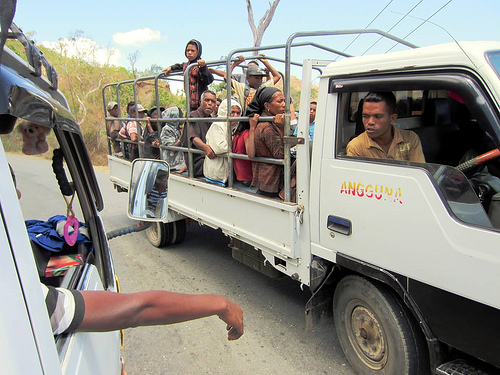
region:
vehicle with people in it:
[98, 40, 480, 318]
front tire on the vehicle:
[323, 272, 424, 367]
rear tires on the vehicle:
[120, 195, 184, 256]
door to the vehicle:
[313, 80, 478, 270]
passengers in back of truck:
[99, 63, 293, 176]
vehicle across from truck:
[2, 31, 124, 372]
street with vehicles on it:
[3, 163, 291, 364]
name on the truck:
[324, 165, 409, 210]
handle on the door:
[321, 211, 354, 238]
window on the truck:
[367, 159, 487, 221]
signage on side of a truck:
[339, 178, 404, 204]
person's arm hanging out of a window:
[39, 282, 246, 341]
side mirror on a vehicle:
[127, 157, 169, 221]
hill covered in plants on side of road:
[7, 37, 311, 166]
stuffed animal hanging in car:
[16, 119, 50, 155]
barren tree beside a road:
[244, 0, 279, 61]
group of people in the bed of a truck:
[103, 40, 315, 203]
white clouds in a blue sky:
[11, 0, 498, 85]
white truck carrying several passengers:
[101, 28, 498, 371]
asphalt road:
[4, 151, 361, 373]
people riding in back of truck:
[104, 42, 315, 200]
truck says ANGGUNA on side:
[338, 179, 405, 204]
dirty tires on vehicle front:
[327, 272, 426, 374]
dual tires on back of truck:
[143, 216, 189, 246]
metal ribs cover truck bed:
[86, 27, 418, 203]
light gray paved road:
[6, 149, 356, 374]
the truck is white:
[101, 49, 494, 372]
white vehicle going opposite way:
[0, 4, 127, 374]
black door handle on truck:
[326, 215, 354, 237]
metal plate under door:
[423, 357, 489, 374]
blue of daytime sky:
[23, 0, 496, 66]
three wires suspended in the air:
[343, 2, 448, 55]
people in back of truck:
[100, 26, 497, 370]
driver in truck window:
[315, 82, 494, 284]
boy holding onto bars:
[157, 37, 214, 107]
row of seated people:
[110, 91, 290, 196]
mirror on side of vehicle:
[106, 158, 172, 243]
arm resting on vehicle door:
[0, 110, 245, 359]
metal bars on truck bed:
[104, 28, 416, 200]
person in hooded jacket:
[203, 99, 240, 184]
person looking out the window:
[353, 90, 425, 179]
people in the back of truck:
[111, 59, 322, 165]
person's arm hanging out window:
[21, 272, 289, 345]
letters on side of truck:
[318, 172, 425, 212]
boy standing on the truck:
[180, 33, 199, 105]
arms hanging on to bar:
[221, 53, 280, 80]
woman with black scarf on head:
[249, 88, 286, 121]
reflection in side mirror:
[131, 145, 171, 225]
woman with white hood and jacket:
[208, 97, 240, 184]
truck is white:
[296, 174, 493, 257]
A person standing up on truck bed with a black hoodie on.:
[161, 39, 214, 111]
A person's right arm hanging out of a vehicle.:
[36, 277, 246, 342]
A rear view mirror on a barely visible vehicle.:
[126, 159, 171, 224]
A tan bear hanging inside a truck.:
[14, 116, 52, 157]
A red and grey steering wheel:
[444, 148, 497, 183]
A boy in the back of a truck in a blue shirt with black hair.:
[294, 100, 318, 136]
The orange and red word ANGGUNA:
[339, 179, 402, 204]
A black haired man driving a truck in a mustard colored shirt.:
[347, 92, 427, 168]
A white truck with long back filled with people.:
[96, 28, 498, 373]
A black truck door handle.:
[326, 214, 352, 236]